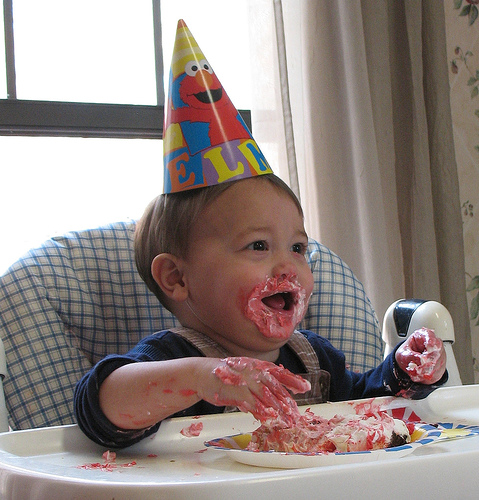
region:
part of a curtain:
[355, 62, 400, 118]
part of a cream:
[342, 407, 375, 437]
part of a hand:
[245, 376, 281, 409]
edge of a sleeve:
[75, 381, 127, 433]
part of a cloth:
[29, 313, 76, 373]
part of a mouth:
[270, 307, 297, 335]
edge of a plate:
[350, 439, 378, 460]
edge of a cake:
[318, 426, 358, 460]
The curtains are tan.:
[296, 0, 473, 329]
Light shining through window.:
[2, 4, 171, 136]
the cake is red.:
[245, 389, 405, 456]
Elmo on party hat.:
[156, 52, 256, 146]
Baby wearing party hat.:
[125, 10, 321, 348]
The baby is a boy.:
[127, 168, 317, 346]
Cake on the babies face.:
[240, 270, 310, 342]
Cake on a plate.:
[210, 403, 477, 466]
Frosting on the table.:
[73, 439, 140, 474]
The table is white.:
[0, 381, 477, 492]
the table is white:
[158, 446, 197, 498]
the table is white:
[153, 442, 226, 488]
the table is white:
[170, 442, 197, 478]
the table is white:
[175, 439, 209, 495]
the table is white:
[175, 470, 196, 483]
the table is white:
[185, 452, 215, 490]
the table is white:
[164, 455, 191, 483]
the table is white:
[170, 473, 224, 496]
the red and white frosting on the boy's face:
[247, 277, 307, 335]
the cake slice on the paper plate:
[229, 405, 409, 453]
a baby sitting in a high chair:
[81, 166, 451, 470]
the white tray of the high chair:
[0, 381, 478, 495]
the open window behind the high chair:
[5, 0, 299, 290]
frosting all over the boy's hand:
[211, 354, 308, 427]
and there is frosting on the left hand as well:
[394, 325, 445, 387]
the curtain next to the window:
[298, 2, 478, 364]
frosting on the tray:
[80, 439, 202, 476]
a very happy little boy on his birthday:
[89, 173, 450, 441]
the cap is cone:
[107, 4, 386, 251]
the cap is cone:
[136, 8, 257, 158]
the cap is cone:
[130, 35, 301, 229]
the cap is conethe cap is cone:
[137, 17, 268, 223]